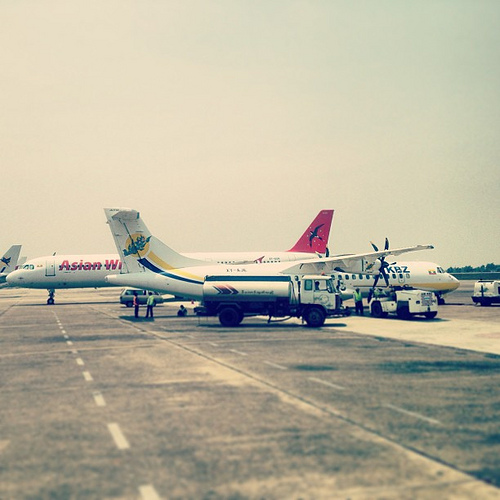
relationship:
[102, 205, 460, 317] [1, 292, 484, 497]
airplane on a landing strip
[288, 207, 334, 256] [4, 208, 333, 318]
stabilizer on a airplane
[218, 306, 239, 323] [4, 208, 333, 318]
wheel on a airplane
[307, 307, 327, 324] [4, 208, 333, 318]
wheel on a airplane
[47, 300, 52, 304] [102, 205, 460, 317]
wheel on a airplane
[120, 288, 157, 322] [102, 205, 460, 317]
people near airplane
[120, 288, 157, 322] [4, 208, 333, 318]
people near airplane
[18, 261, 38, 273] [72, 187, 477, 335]
cockpit of a plane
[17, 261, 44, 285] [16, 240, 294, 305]
cockpit of a plane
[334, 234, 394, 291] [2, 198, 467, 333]
propeller on front of a plane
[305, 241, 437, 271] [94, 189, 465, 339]
wing of plane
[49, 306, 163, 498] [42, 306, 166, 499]
lines on landing strip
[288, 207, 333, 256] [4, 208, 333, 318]
tail fin of airplane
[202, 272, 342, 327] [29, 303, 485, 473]
truck driving on street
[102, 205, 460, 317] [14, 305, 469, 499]
airplane parked on tarmac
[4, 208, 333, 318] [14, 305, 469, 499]
airplane parked on tarmac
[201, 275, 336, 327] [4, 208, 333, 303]
truck fueling airplane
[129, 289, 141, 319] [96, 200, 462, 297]
person standing below airplane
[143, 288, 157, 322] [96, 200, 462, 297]
person standing below airplane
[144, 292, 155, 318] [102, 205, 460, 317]
person standing beside airplane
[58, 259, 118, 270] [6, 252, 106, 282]
writing on plane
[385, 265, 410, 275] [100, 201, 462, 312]
writing on plane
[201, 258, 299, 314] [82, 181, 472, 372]
logo on plane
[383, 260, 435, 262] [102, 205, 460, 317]
edge belonging to airplane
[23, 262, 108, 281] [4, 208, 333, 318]
side belonging to airplane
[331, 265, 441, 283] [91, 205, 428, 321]
side belonging to plane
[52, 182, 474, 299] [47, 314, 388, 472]
airplane parked on runway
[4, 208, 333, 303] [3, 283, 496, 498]
airplane parked on runway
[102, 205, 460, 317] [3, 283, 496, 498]
airplane parked on runway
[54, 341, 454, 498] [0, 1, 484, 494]
runway seen during day